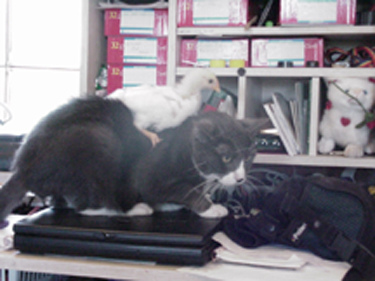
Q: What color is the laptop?
A: Black.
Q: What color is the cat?
A: Grey and white.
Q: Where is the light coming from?
A: Window.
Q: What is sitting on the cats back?
A: A chicken.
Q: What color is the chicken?
A: White.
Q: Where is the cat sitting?
A: Laptop.